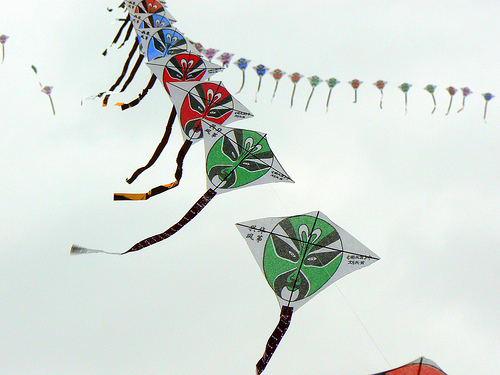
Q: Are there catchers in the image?
A: No, there are no catchers.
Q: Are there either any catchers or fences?
A: No, there are no catchers or fences.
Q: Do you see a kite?
A: Yes, there is a kite.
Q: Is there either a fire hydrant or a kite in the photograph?
A: Yes, there is a kite.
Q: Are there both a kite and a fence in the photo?
A: No, there is a kite but no fences.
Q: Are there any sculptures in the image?
A: No, there are no sculptures.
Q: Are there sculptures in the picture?
A: No, there are no sculptures.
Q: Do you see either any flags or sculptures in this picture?
A: No, there are no sculptures or flags.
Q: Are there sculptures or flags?
A: No, there are no sculptures or flags.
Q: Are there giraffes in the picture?
A: No, there are no giraffes.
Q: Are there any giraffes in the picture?
A: No, there are no giraffes.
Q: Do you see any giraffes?
A: No, there are no giraffes.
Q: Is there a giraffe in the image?
A: No, there are no giraffes.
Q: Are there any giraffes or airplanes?
A: No, there are no giraffes or airplanes.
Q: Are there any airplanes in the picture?
A: No, there are no airplanes.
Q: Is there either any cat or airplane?
A: No, there are no airplanes or cats.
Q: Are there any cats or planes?
A: No, there are no planes or cats.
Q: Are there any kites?
A: Yes, there is a kite.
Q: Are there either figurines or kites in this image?
A: Yes, there is a kite.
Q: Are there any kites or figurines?
A: Yes, there is a kite.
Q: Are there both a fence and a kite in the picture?
A: No, there is a kite but no fences.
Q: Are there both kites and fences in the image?
A: No, there is a kite but no fences.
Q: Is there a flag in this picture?
A: No, there are no flags.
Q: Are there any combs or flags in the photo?
A: No, there are no flags or combs.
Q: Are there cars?
A: No, there are no cars.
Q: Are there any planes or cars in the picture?
A: No, there are no cars or planes.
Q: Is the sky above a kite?
A: Yes, the sky is above a kite.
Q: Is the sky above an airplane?
A: No, the sky is above a kite.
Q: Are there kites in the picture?
A: Yes, there is a kite.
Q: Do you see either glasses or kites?
A: Yes, there is a kite.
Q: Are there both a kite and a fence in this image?
A: No, there is a kite but no fences.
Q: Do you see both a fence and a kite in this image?
A: No, there is a kite but no fences.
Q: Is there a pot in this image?
A: No, there are no pots.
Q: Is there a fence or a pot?
A: No, there are no pots or fences.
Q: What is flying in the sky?
A: The kite is flying in the sky.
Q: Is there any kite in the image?
A: Yes, there is a kite.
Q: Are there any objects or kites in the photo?
A: Yes, there is a kite.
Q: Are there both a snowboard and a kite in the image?
A: No, there is a kite but no snowboards.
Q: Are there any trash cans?
A: No, there are no trash cans.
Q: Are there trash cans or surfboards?
A: No, there are no trash cans or surfboards.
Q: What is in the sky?
A: The kite is in the sky.